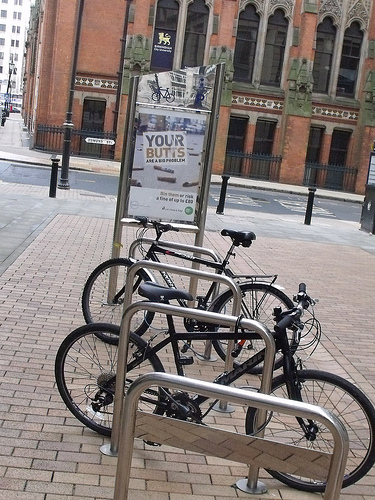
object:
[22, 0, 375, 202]
building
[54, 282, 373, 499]
bikes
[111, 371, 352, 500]
racks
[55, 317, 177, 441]
wheel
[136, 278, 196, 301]
seat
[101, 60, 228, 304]
support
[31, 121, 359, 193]
fence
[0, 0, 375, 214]
background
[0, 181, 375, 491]
sidewalk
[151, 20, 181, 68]
banner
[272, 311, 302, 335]
handle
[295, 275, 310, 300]
handle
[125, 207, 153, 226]
handle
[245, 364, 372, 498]
wheel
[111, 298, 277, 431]
rack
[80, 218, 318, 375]
bike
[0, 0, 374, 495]
outside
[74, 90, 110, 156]
door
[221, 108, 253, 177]
door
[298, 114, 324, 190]
door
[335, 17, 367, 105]
window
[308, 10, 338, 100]
window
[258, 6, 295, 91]
window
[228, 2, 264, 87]
window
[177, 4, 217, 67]
window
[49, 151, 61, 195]
post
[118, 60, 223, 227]
sign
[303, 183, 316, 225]
post